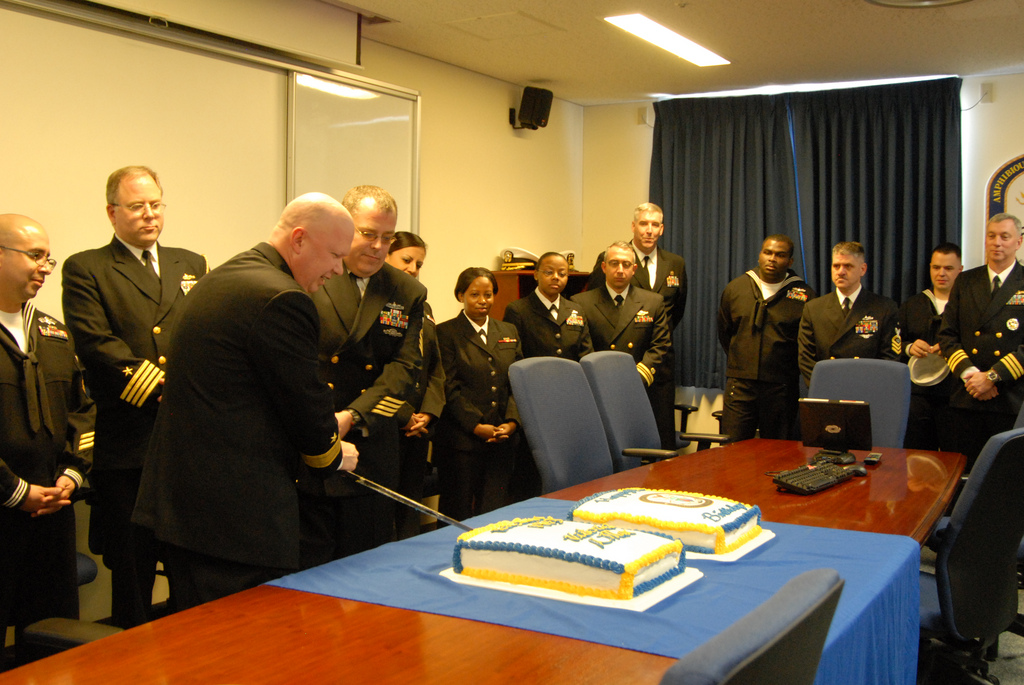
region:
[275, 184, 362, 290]
the bald head of the man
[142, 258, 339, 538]
the jacket is black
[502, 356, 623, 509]
the seat is blue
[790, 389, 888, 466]
the computer is black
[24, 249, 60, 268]
the glasses are clear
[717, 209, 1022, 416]
people are standing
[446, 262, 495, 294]
the hair is black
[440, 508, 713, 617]
sheet cake on right side of cloth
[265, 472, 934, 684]
tablecloth on middle of table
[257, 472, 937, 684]
tablecloth on table is blue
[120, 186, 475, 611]
man cutting into cake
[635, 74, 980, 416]
curtains hanging in front of window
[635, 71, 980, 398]
curtains hangin are blue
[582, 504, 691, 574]
Two cakes on a tables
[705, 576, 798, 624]
A blue table cloth with cake on it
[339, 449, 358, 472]
A hand holding a knife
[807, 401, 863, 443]
The back of a computer screen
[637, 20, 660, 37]
A shining light in the ceiling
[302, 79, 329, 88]
Reflection of light on glass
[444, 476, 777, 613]
Two cakes on table.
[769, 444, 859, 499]
Keyboard on table.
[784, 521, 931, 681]
Blue tablecloth on table.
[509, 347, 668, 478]
Blue chairs along table.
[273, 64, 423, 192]
White board in back of room.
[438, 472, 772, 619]
Cakes decorated with blue and yellow frosting.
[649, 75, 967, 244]
Blue pleated drapes over window.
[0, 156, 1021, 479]
Military personal in gathered in room.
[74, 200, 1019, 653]
table in the background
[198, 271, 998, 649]
glossy table in the background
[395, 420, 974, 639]
cake on the table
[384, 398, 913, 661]
two cakes on the table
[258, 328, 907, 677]
blue cloth on the table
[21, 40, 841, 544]
suits on on the people